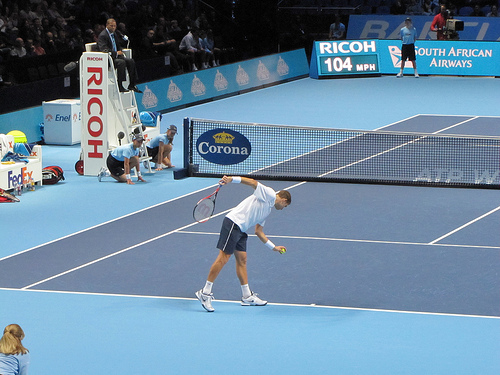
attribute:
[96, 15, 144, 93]
suit — black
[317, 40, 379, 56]
advertisement — for Ricoh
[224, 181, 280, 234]
shirt — white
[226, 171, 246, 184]
hand — man's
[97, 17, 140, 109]
official — tennis game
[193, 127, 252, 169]
sign — blue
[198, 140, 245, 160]
letters — white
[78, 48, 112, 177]
logo — Ricoh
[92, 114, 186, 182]
seat — a base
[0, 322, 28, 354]
hair — blond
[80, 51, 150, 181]
chair — referee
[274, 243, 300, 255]
ball — yellow tennis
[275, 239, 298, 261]
ball — yellow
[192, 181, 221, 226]
racket — tennis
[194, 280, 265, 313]
shoes — white, tennis